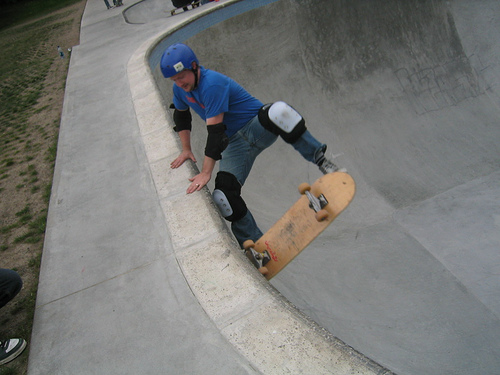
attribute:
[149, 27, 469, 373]
ramp — paved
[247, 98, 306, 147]
pads — black, white, knee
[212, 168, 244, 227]
pads — black, white, knee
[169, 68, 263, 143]
t shirt — is blue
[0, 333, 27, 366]
shoe — black, white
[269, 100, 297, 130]
pads — black, white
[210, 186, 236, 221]
pads — white, black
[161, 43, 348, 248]
man — riding, wearing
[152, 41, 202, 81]
helmet — blue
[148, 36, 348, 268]
person — doing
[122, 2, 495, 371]
ring — concrete, skating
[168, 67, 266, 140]
shirt — blue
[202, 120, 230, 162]
elbow pads — black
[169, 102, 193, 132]
elbow pads — black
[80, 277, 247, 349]
pavement — gray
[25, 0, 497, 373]
pavement — gray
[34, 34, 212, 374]
pavement — gray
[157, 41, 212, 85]
helmet — blue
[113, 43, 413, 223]
man — wearing